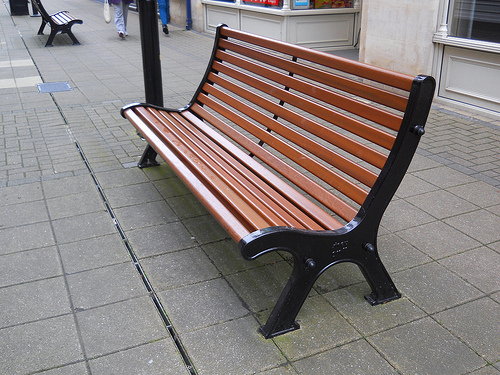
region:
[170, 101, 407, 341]
the bench is shiny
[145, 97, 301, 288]
the bench is shiny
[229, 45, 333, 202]
the bench is shiny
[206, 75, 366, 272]
the bench is shiny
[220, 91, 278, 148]
the bench is shiny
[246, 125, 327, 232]
the bench is shiny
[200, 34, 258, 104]
the bench is shiny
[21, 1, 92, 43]
A bench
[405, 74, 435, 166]
the side of the bench is black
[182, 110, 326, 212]
The bench is brown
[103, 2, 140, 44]
A person walking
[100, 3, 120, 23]
A white bag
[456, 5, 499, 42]
A window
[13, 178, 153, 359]
The sidewalk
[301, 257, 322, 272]
A bolt on the bench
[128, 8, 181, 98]
A black pole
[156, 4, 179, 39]
a person walking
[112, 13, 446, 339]
a brown and black bench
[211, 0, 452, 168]
a restbench of brown planks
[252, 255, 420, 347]
black legs on right side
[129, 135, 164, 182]
black legs on left side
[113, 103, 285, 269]
sit of bench is long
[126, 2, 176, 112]
black pole next to a bench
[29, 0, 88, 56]
bench is brown and black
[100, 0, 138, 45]
legs of person with blue jeans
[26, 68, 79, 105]
a drain in the sidewalk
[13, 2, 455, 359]
sidewalk with two benches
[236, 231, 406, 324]
black steel bench sides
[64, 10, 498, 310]
a metel bench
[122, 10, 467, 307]
a metal bench outside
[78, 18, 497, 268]
a metal bench on the side walk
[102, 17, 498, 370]
a two color bench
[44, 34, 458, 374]
a bench on the sidewalk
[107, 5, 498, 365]
a bench next to a pole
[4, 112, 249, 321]
a sidewalk made of squares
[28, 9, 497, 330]
two benches on the sidewalk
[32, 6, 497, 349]
two benches facing opposite ways